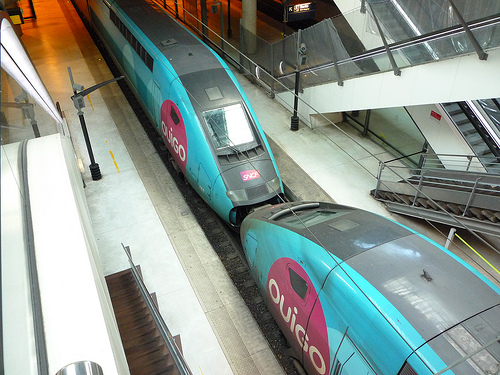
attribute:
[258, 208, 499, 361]
train engine — light blue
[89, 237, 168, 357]
staircase — metal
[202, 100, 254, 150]
windshield — train, engine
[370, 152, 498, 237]
staircase — metal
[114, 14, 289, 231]
train engine — blue